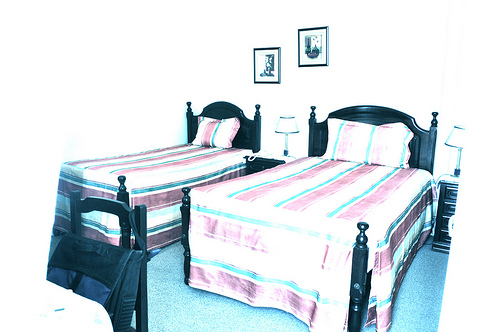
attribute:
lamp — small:
[249, 107, 323, 168]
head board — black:
[305, 101, 440, 173]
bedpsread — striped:
[250, 136, 425, 252]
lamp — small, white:
[424, 127, 481, 194]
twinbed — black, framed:
[53, 99, 272, 257]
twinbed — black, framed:
[184, 104, 441, 329]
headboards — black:
[183, 100, 439, 175]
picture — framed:
[252, 19, 351, 87]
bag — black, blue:
[42, 217, 147, 330]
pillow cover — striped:
[320, 115, 411, 170]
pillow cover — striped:
[190, 114, 240, 150]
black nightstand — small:
[430, 180, 460, 252]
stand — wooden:
[423, 153, 460, 278]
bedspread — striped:
[186, 154, 436, 329]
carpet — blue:
[167, 254, 232, 327]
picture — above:
[253, 47, 279, 85]